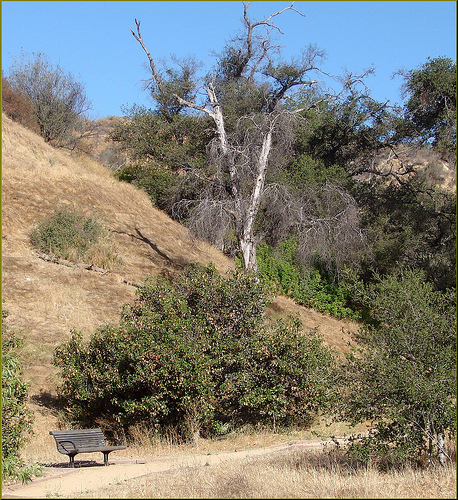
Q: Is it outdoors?
A: Yes, it is outdoors.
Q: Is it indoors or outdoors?
A: It is outdoors.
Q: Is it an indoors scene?
A: No, it is outdoors.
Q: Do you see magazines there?
A: No, there are no magazines.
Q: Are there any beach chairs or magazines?
A: No, there are no magazines or beach chairs.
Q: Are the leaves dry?
A: Yes, the leaves are dry.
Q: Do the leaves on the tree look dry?
A: Yes, the leaves are dry.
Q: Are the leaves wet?
A: No, the leaves are dry.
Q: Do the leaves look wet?
A: No, the leaves are dry.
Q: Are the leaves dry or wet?
A: The leaves are dry.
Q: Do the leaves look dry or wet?
A: The leaves are dry.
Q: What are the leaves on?
A: The leaves are on the tree.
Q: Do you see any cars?
A: No, there are no cars.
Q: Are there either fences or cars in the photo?
A: No, there are no cars or fences.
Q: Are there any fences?
A: No, there are no fences.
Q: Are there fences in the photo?
A: No, there are no fences.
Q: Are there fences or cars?
A: No, there are no fences or cars.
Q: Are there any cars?
A: No, there are no cars.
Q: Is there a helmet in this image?
A: No, there are no helmets.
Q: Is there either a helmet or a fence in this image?
A: No, there are no helmets or fences.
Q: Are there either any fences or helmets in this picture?
A: No, there are no helmets or fences.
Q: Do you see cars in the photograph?
A: No, there are no cars.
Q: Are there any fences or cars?
A: No, there are no cars or fences.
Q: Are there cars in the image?
A: No, there are no cars.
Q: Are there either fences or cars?
A: No, there are no cars or fences.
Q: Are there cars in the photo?
A: No, there are no cars.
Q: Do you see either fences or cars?
A: No, there are no cars or fences.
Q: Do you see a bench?
A: Yes, there is a bench.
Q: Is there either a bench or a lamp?
A: Yes, there is a bench.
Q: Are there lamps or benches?
A: Yes, there is a bench.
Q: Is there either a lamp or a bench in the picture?
A: Yes, there is a bench.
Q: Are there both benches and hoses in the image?
A: No, there is a bench but no hoses.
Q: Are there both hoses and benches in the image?
A: No, there is a bench but no hoses.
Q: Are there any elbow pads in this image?
A: No, there are no elbow pads.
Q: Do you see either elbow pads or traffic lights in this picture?
A: No, there are no elbow pads or traffic lights.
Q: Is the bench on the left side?
A: Yes, the bench is on the left of the image.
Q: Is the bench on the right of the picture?
A: No, the bench is on the left of the image.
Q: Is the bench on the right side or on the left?
A: The bench is on the left of the image.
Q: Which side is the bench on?
A: The bench is on the left of the image.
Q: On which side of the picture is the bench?
A: The bench is on the left of the image.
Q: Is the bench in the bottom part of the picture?
A: Yes, the bench is in the bottom of the image.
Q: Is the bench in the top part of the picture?
A: No, the bench is in the bottom of the image.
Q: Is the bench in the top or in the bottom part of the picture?
A: The bench is in the bottom of the image.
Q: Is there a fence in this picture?
A: No, there are no fences.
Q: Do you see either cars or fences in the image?
A: No, there are no fences or cars.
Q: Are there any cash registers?
A: No, there are no cash registers.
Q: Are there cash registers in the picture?
A: No, there are no cash registers.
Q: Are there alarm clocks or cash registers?
A: No, there are no cash registers or alarm clocks.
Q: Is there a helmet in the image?
A: No, there are no helmets.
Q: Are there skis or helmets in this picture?
A: No, there are no helmets or skis.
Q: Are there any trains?
A: No, there are no trains.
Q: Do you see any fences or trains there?
A: No, there are no trains or fences.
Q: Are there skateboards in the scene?
A: No, there are no skateboards.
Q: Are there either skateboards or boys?
A: No, there are no skateboards or boys.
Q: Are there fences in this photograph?
A: No, there are no fences.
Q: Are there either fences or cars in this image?
A: No, there are no fences or cars.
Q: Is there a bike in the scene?
A: No, there are no bikes.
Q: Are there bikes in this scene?
A: No, there are no bikes.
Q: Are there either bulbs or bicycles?
A: No, there are no bicycles or bulbs.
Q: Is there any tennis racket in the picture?
A: No, there are no rackets.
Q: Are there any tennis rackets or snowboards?
A: No, there are no tennis rackets or snowboards.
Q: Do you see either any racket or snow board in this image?
A: No, there are no rackets or snowboards.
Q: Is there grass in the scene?
A: Yes, there is grass.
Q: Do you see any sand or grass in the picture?
A: Yes, there is grass.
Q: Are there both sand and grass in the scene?
A: No, there is grass but no sand.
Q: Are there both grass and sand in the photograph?
A: No, there is grass but no sand.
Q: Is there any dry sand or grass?
A: Yes, there is dry grass.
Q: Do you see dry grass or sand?
A: Yes, there is dry grass.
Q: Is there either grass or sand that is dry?
A: Yes, the grass is dry.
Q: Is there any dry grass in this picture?
A: Yes, there is dry grass.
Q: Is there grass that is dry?
A: Yes, there is dry grass.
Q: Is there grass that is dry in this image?
A: Yes, there is dry grass.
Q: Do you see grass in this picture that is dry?
A: Yes, there is grass that is dry.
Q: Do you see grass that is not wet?
A: Yes, there is dry grass.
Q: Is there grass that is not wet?
A: Yes, there is dry grass.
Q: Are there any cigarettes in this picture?
A: No, there are no cigarettes.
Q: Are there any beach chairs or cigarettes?
A: No, there are no cigarettes or beach chairs.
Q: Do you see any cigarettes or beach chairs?
A: No, there are no cigarettes or beach chairs.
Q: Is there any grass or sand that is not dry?
A: No, there is grass but it is dry.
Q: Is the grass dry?
A: Yes, the grass is dry.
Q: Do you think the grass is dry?
A: Yes, the grass is dry.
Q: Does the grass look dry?
A: Yes, the grass is dry.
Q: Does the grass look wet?
A: No, the grass is dry.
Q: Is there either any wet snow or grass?
A: No, there is grass but it is dry.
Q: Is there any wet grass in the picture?
A: No, there is grass but it is dry.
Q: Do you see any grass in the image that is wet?
A: No, there is grass but it is dry.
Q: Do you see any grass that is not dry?
A: No, there is grass but it is dry.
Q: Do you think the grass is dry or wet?
A: The grass is dry.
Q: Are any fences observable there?
A: No, there are no fences.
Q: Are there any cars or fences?
A: No, there are no fences or cars.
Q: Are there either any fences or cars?
A: No, there are no fences or cars.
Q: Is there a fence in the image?
A: No, there are no fences.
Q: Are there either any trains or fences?
A: No, there are no fences or trains.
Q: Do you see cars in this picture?
A: No, there are no cars.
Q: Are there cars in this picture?
A: No, there are no cars.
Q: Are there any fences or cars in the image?
A: No, there are no cars or fences.